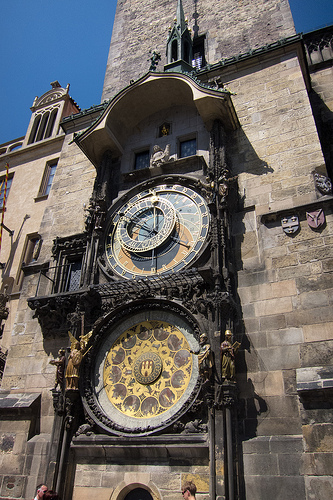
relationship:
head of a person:
[178, 478, 199, 497] [181, 480, 199, 499]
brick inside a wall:
[252, 295, 293, 318] [1, 53, 331, 500]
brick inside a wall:
[300, 324, 332, 344] [1, 53, 331, 500]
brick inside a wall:
[265, 325, 307, 347] [1, 53, 331, 500]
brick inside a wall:
[240, 454, 280, 476] [1, 53, 331, 500]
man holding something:
[218, 328, 241, 383] [231, 340, 241, 354]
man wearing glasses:
[30, 482, 51, 500] [36, 486, 48, 494]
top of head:
[184, 482, 195, 488] [178, 478, 199, 497]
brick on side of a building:
[252, 295, 293, 318] [0, 0, 332, 500]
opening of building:
[110, 483, 157, 498] [0, 0, 332, 500]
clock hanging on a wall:
[94, 174, 214, 280] [1, 53, 331, 500]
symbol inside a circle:
[155, 387, 178, 408] [77, 298, 209, 440]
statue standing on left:
[64, 330, 95, 392] [60, 296, 135, 433]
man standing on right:
[218, 328, 241, 383] [161, 300, 231, 437]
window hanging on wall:
[176, 131, 197, 158] [1, 53, 331, 500]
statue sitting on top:
[148, 142, 178, 167] [121, 157, 209, 181]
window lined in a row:
[47, 107, 60, 140] [27, 103, 61, 143]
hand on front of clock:
[146, 187, 161, 231] [94, 174, 214, 280]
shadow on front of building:
[225, 93, 271, 444] [0, 0, 332, 500]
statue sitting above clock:
[148, 142, 178, 167] [94, 174, 214, 280]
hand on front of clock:
[116, 209, 154, 232] [94, 174, 214, 280]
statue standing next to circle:
[64, 330, 95, 392] [77, 298, 209, 440]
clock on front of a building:
[94, 174, 214, 280] [0, 0, 332, 500]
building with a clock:
[0, 0, 332, 500] [94, 174, 214, 280]